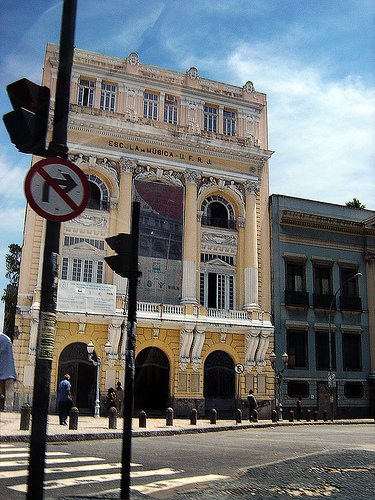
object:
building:
[2, 40, 276, 409]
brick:
[163, 332, 179, 344]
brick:
[91, 329, 107, 340]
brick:
[33, 241, 41, 248]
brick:
[20, 346, 29, 353]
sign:
[24, 155, 93, 224]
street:
[2, 410, 370, 494]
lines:
[0, 441, 231, 499]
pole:
[24, 0, 81, 495]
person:
[2, 325, 14, 412]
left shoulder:
[0, 333, 16, 390]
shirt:
[56, 378, 71, 402]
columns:
[241, 171, 262, 314]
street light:
[86, 339, 95, 353]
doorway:
[133, 344, 173, 417]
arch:
[133, 340, 173, 414]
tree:
[1, 241, 21, 347]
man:
[56, 371, 73, 425]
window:
[77, 77, 97, 108]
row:
[74, 74, 122, 115]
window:
[196, 190, 236, 318]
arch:
[197, 184, 245, 231]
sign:
[36, 312, 58, 361]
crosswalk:
[2, 437, 230, 499]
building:
[270, 195, 374, 412]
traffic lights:
[0, 76, 48, 154]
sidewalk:
[0, 409, 370, 439]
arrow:
[41, 172, 76, 202]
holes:
[242, 451, 372, 500]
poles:
[327, 270, 361, 421]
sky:
[270, 0, 375, 198]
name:
[107, 139, 212, 165]